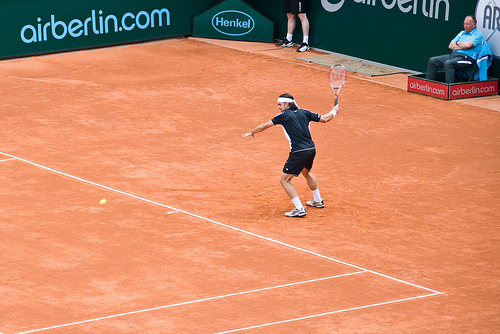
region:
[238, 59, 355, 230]
man playing tennis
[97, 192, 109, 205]
tennis ball in the air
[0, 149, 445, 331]
white lines on the court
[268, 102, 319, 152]
navy blue shirt on the tennis player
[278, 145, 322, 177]
black shorts on the athlete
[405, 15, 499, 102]
person watching the tennis game in a chair box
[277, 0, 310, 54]
person standing against the wall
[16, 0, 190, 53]
website advertisement on the wall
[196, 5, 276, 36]
advertisement on the wall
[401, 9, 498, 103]
the man is sitting on a chair surrounded by a box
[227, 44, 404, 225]
the man is playing tennis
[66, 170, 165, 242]
the ball is lime green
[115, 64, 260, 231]
the dirt is reddish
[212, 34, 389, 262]
the man is swinging a racket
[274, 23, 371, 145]
the man is holding a tennis racket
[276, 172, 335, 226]
the man is wearing socks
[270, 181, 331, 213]
the socks are white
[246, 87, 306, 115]
man is wearing a headband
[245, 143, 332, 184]
the man is wearing shorts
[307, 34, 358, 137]
the racket has a W on it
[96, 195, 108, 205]
yellow tennis ball in the air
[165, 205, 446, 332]
white line on the tennis court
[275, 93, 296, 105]
white headband on the player's head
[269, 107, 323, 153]
black shirt on the player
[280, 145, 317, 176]
black shorts on the player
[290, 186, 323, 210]
white socks on the player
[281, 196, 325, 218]
white and red shoes on the player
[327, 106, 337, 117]
white wristband on the player's arm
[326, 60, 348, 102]
red, white and black tennis racket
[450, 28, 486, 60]
man wearing a blue shirt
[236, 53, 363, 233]
A man playing tennis.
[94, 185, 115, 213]
Tennis ball flying through air.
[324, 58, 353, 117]
Red and white tennis racket.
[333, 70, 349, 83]
Letter W on a racket.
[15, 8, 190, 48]
An ad on the court wall.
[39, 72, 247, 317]
A large clay tennis court.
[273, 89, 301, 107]
Bandanna around a man's head.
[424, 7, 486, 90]
Judge sitting in a chair.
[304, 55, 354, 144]
An arm swinging a racket.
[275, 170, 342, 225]
Shoes on a man.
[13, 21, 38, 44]
The letter is blue.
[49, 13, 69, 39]
The letter is blue.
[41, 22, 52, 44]
The letter is blue.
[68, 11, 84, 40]
The letter is blue.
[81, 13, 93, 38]
The letter is blue.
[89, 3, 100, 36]
The letter is blue.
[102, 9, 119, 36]
The letter is blue.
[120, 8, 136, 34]
The letter is blue.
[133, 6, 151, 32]
The letter is blue.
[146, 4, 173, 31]
The letter is blue.